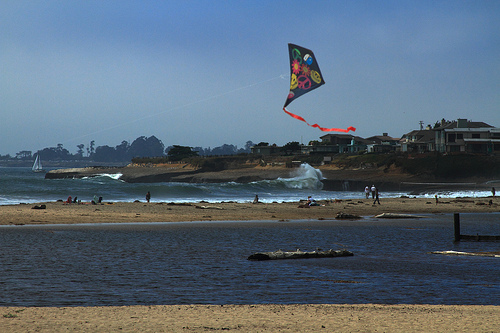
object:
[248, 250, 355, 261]
log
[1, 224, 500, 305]
water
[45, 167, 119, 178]
pier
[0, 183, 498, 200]
water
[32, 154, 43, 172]
sailboat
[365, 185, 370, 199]
people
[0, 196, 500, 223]
shoreline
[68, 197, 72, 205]
people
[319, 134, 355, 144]
house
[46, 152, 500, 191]
hillside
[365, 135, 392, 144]
house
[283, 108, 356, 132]
ribbon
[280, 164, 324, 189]
waves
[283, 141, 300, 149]
tree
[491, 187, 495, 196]
person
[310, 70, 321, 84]
smiley face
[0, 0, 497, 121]
sky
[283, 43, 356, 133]
kite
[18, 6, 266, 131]
air